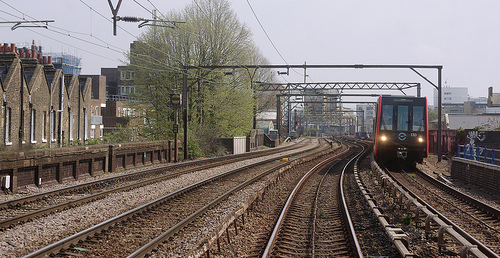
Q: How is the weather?
A: It is overcast.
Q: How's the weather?
A: It is overcast.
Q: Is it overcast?
A: Yes, it is overcast.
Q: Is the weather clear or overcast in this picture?
A: It is overcast.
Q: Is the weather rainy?
A: No, it is overcast.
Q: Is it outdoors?
A: Yes, it is outdoors.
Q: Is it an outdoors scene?
A: Yes, it is outdoors.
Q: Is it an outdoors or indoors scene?
A: It is outdoors.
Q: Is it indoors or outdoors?
A: It is outdoors.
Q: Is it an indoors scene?
A: No, it is outdoors.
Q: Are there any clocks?
A: No, there are no clocks.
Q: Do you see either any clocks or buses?
A: No, there are no clocks or buses.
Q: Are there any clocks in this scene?
A: No, there are no clocks.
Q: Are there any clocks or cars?
A: No, there are no clocks or cars.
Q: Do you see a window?
A: Yes, there is a window.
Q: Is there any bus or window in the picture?
A: Yes, there is a window.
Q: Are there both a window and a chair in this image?
A: No, there is a window but no chairs.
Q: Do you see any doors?
A: No, there are no doors.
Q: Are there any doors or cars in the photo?
A: No, there are no doors or cars.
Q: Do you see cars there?
A: No, there are no cars.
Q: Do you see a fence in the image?
A: Yes, there is a fence.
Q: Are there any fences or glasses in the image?
A: Yes, there is a fence.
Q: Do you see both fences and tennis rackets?
A: No, there is a fence but no rackets.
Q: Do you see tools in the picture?
A: No, there are no tools.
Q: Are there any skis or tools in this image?
A: No, there are no tools or skis.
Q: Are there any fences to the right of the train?
A: Yes, there is a fence to the right of the train.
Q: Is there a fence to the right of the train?
A: Yes, there is a fence to the right of the train.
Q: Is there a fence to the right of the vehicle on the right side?
A: Yes, there is a fence to the right of the train.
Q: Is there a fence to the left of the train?
A: No, the fence is to the right of the train.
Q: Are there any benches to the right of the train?
A: No, there is a fence to the right of the train.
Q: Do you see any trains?
A: Yes, there is a train.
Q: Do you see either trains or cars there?
A: Yes, there is a train.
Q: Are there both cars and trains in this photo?
A: No, there is a train but no cars.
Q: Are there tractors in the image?
A: No, there are no tractors.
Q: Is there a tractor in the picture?
A: No, there are no tractors.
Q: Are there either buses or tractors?
A: No, there are no tractors or buses.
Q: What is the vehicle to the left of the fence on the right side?
A: The vehicle is a train.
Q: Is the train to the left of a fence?
A: Yes, the train is to the left of a fence.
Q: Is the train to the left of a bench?
A: No, the train is to the left of a fence.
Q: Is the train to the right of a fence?
A: No, the train is to the left of a fence.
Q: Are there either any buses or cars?
A: No, there are no cars or buses.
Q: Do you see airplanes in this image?
A: No, there are no airplanes.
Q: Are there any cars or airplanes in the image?
A: No, there are no airplanes or cars.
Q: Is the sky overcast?
A: Yes, the sky is overcast.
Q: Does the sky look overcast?
A: Yes, the sky is overcast.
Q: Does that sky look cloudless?
A: No, the sky is overcast.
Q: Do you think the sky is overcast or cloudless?
A: The sky is overcast.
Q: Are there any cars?
A: No, there are no cars.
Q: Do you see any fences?
A: Yes, there is a fence.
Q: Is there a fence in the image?
A: Yes, there is a fence.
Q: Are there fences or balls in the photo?
A: Yes, there is a fence.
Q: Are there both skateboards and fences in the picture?
A: No, there is a fence but no skateboards.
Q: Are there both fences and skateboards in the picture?
A: No, there is a fence but no skateboards.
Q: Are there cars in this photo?
A: No, there are no cars.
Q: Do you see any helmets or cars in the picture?
A: No, there are no cars or helmets.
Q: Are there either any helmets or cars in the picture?
A: No, there are no cars or helmets.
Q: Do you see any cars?
A: No, there are no cars.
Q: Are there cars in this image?
A: No, there are no cars.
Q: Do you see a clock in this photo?
A: No, there are no clocks.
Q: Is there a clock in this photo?
A: No, there are no clocks.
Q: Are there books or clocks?
A: No, there are no clocks or books.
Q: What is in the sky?
A: The wires are in the sky.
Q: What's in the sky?
A: The wires are in the sky.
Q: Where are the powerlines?
A: The powerlines are in the sky.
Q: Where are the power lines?
A: The powerlines are in the sky.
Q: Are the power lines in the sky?
A: Yes, the power lines are in the sky.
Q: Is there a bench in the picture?
A: No, there are no benches.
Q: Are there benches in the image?
A: No, there are no benches.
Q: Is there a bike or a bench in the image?
A: No, there are no benches or bikes.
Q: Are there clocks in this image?
A: No, there are no clocks.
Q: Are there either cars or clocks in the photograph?
A: No, there are no clocks or cars.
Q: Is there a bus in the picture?
A: No, there are no buses.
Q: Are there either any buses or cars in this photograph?
A: No, there are no buses or cars.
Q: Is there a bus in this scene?
A: No, there are no buses.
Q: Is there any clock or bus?
A: No, there are no buses or clocks.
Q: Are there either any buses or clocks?
A: No, there are no buses or clocks.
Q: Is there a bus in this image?
A: No, there are no buses.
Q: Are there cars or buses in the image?
A: No, there are no buses or cars.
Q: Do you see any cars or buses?
A: No, there are no buses or cars.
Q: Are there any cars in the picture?
A: No, there are no cars.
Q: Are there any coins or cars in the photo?
A: No, there are no cars or coins.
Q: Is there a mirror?
A: No, there are no mirrors.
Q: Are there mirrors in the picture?
A: No, there are no mirrors.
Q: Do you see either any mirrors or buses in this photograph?
A: No, there are no mirrors or buses.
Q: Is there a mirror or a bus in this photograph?
A: No, there are no mirrors or buses.